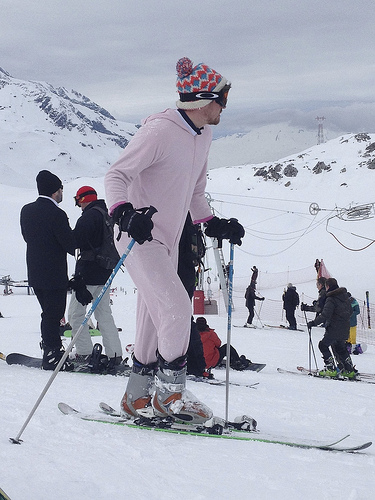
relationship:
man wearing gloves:
[98, 49, 232, 414] [111, 202, 254, 255]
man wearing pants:
[27, 171, 67, 358] [36, 281, 67, 371]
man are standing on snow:
[104, 58, 246, 423] [38, 425, 372, 486]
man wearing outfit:
[104, 58, 246, 423] [116, 115, 214, 385]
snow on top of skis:
[69, 407, 113, 417] [51, 392, 372, 459]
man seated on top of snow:
[104, 58, 246, 423] [246, 343, 277, 361]